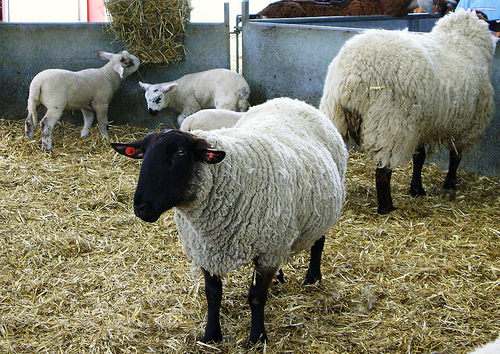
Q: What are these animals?
A: Sheep.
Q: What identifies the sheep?
A: Tags in ears.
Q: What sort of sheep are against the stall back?
A: Two baby lambs.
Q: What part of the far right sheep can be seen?
A: The back part.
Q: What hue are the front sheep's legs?
A: Black.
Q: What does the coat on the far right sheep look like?
A: Thick, white and dirty.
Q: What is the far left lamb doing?
A: Chewing on hay.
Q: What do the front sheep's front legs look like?
A: Black and furry.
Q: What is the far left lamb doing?
A: Eating the hay.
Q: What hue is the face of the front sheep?
A: Black.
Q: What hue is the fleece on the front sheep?
A: Dirty white.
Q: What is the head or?
A: A sheep.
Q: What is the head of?
A: A sheep.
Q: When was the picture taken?
A: Daytime.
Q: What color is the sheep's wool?
A: White.